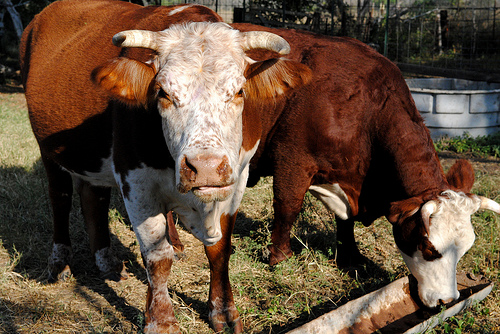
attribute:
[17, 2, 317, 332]
cow — brown, standing, white, eating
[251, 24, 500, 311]
cow — brown, eating, white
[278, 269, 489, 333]
trough — metal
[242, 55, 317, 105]
ear — furry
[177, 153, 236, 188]
nose — wet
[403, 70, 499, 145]
container — white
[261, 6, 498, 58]
fence — wire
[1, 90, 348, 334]
grass — green, brown